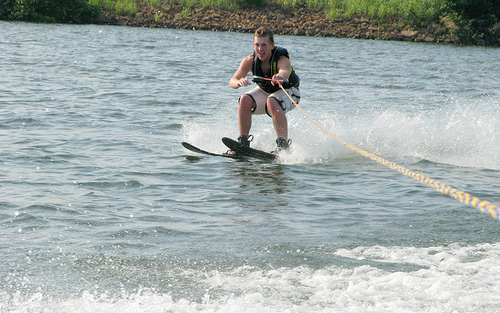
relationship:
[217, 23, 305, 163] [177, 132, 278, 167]
man on water skis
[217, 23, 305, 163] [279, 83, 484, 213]
man with tow rope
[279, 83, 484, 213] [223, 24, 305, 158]
tow rope for skier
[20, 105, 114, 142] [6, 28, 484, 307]
ripples on water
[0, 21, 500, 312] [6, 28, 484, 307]
ripples on water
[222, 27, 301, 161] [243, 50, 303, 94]
man in jacket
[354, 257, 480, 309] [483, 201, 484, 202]
wake of boat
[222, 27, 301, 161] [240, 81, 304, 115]
man in trunks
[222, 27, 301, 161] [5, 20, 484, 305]
man enjoying adventure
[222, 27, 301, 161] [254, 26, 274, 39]
man has hair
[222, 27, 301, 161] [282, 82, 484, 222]
man holding rope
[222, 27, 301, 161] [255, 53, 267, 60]
man has teeth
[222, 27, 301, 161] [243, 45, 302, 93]
man wearing vest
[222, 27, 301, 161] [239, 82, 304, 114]
man wearing shorts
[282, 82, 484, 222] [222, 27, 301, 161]
rope pulling man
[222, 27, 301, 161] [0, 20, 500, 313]
man skiing water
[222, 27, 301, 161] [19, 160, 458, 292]
man on water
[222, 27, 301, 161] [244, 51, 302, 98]
man wearing jacket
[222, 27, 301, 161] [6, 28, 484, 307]
man on water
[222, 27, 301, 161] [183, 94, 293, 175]
man wearing kneboarding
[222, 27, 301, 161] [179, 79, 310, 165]
man wearing kneeboarding